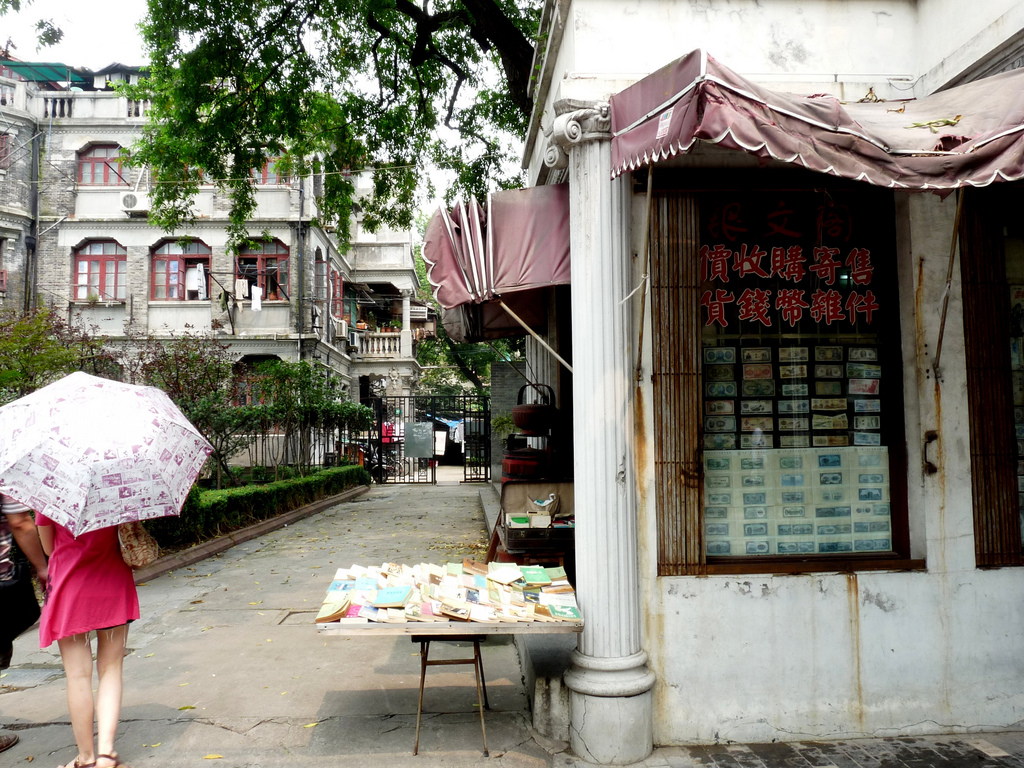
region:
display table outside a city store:
[318, 555, 582, 756]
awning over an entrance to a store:
[421, 182, 573, 313]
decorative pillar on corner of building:
[538, 105, 656, 758]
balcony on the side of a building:
[336, 241, 423, 374]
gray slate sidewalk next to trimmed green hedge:
[0, 475, 531, 766]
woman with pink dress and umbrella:
[0, 371, 210, 758]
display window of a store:
[658, 160, 905, 575]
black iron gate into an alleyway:
[355, 391, 496, 490]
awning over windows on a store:
[613, 48, 1018, 197]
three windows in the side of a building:
[63, 232, 289, 313]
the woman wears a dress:
[38, 521, 130, 652]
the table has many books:
[318, 563, 574, 639]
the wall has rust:
[644, 184, 958, 739]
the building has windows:
[5, 70, 416, 402]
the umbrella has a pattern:
[6, 372, 212, 532]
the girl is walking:
[3, 369, 213, 763]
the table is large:
[319, 550, 569, 753]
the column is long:
[562, 94, 668, 763]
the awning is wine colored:
[427, 83, 1022, 318]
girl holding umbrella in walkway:
[1, 370, 201, 763]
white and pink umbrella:
[12, 361, 191, 540]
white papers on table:
[323, 545, 536, 616]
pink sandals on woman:
[71, 743, 113, 763]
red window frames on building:
[65, 229, 129, 302]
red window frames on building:
[75, 134, 137, 199]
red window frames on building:
[226, 238, 293, 303]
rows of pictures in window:
[662, 168, 882, 548]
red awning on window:
[631, 57, 1023, 157]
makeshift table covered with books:
[309, 554, 591, 760]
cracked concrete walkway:
[6, 481, 575, 766]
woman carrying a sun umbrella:
[0, 364, 220, 766]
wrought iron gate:
[373, 389, 495, 488]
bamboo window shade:
[654, 163, 709, 578]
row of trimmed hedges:
[191, 459, 368, 530]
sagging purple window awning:
[602, 40, 1020, 190]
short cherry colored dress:
[30, 506, 142, 647]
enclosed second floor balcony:
[340, 269, 414, 359]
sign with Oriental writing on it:
[695, 232, 889, 332]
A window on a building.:
[237, 248, 289, 296]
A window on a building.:
[152, 239, 209, 294]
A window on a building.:
[66, 253, 128, 304]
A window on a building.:
[76, 147, 138, 183]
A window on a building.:
[161, 157, 206, 184]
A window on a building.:
[243, 155, 298, 193]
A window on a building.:
[129, 92, 168, 119]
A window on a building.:
[5, 84, 34, 108]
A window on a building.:
[679, 198, 891, 571]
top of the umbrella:
[0, 347, 256, 572]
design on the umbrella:
[13, 339, 219, 564]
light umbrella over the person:
[0, 335, 219, 591]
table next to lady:
[309, 533, 635, 692]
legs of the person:
[33, 612, 171, 762]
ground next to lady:
[187, 538, 308, 732]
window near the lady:
[596, 195, 945, 614]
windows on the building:
[31, 138, 342, 361]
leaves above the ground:
[122, 70, 405, 260]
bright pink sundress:
[26, 503, 141, 658]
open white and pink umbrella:
[8, 367, 214, 533]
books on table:
[329, 559, 580, 629]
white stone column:
[547, 94, 668, 765]